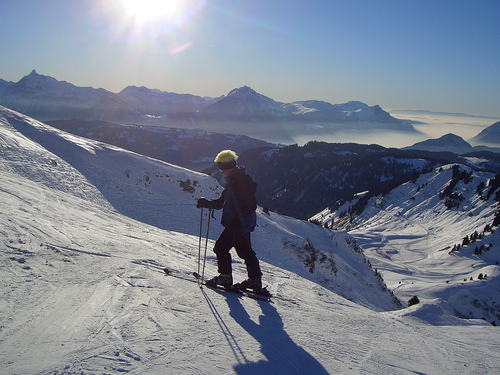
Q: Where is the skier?
A: In the mountains.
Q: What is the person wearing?
A: Warm clothing.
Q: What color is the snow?
A: White.